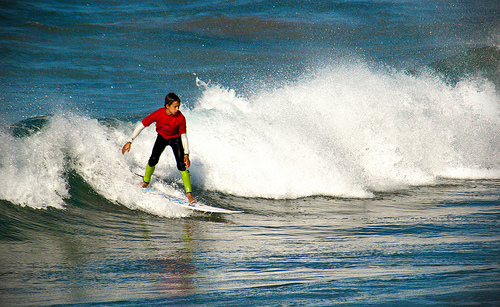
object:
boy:
[120, 92, 196, 208]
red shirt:
[140, 108, 188, 139]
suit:
[125, 103, 205, 196]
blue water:
[0, 1, 499, 306]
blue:
[402, 276, 500, 307]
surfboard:
[126, 162, 244, 214]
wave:
[0, 36, 498, 228]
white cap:
[0, 50, 498, 220]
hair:
[163, 93, 179, 110]